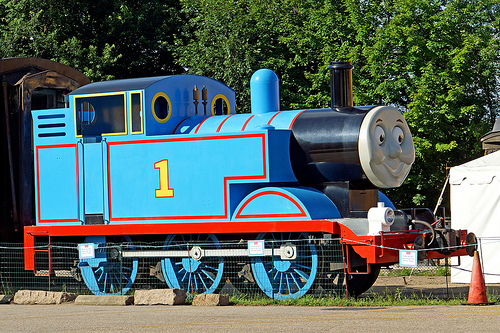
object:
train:
[0, 58, 480, 307]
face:
[357, 105, 417, 189]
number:
[152, 158, 174, 196]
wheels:
[250, 231, 318, 301]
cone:
[460, 250, 487, 304]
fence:
[0, 238, 500, 305]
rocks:
[131, 287, 189, 307]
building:
[447, 148, 500, 285]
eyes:
[372, 122, 385, 146]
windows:
[149, 89, 173, 122]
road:
[0, 299, 499, 333]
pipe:
[328, 60, 354, 106]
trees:
[0, 0, 178, 84]